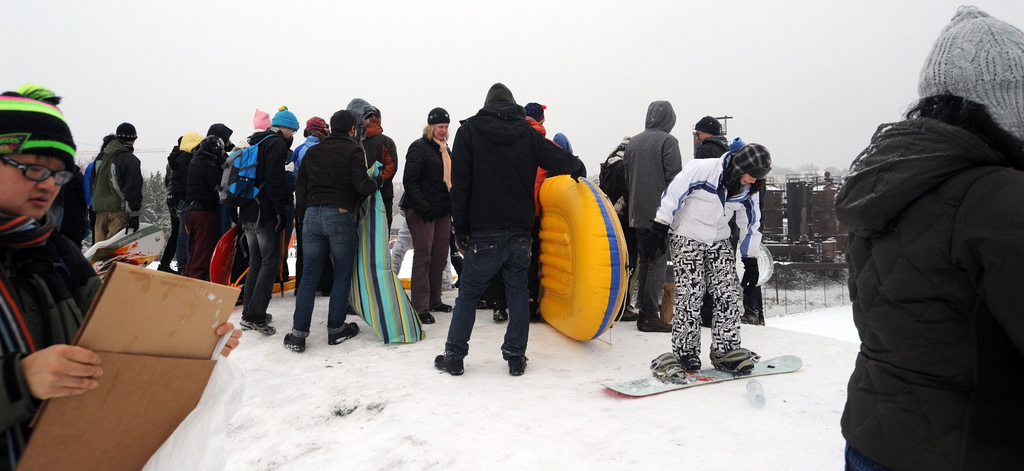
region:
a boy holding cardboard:
[0, 70, 261, 463]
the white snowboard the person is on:
[599, 350, 809, 398]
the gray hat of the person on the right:
[897, 0, 1019, 125]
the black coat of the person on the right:
[830, 97, 1021, 467]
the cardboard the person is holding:
[21, 263, 250, 466]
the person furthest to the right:
[828, 4, 1021, 467]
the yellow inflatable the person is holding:
[536, 170, 634, 347]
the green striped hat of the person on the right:
[0, 88, 98, 164]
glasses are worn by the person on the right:
[3, 152, 98, 197]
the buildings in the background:
[752, 167, 869, 307]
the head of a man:
[2, 83, 78, 243]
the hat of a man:
[2, 78, 86, 162]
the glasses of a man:
[11, 151, 81, 189]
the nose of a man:
[32, 168, 64, 197]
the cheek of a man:
[8, 162, 28, 202]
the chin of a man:
[17, 203, 55, 220]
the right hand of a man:
[32, 341, 110, 428]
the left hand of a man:
[190, 309, 260, 355]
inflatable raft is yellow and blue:
[535, 165, 635, 347]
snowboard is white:
[590, 348, 812, 391]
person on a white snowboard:
[614, 132, 798, 408]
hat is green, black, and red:
[1, 83, 79, 170]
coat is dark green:
[830, 103, 1021, 443]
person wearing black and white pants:
[650, 141, 765, 377]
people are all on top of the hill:
[10, 81, 1019, 468]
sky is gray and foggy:
[0, 7, 1019, 201]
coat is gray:
[621, 100, 673, 231]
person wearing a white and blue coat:
[664, 109, 764, 382]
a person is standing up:
[656, 141, 787, 391]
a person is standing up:
[0, 95, 131, 451]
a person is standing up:
[82, 111, 134, 258]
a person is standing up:
[110, 94, 167, 247]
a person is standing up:
[158, 101, 226, 267]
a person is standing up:
[223, 88, 301, 339]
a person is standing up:
[286, 95, 385, 351]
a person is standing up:
[404, 82, 461, 326]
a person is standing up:
[613, 95, 684, 321]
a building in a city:
[776, 171, 812, 239]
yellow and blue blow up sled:
[537, 167, 633, 346]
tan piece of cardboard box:
[6, 259, 244, 466]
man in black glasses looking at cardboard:
[4, 82, 240, 466]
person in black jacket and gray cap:
[827, 5, 1023, 464]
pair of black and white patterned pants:
[670, 229, 741, 365]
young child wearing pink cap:
[249, 106, 275, 130]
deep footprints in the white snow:
[211, 331, 446, 467]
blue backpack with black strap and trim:
[219, 131, 265, 224]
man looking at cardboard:
[2, 80, 236, 466]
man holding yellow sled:
[447, 85, 628, 384]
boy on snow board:
[605, 131, 820, 395]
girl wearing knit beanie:
[820, 1, 1020, 463]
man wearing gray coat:
[614, 98, 688, 336]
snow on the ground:
[15, 250, 894, 460]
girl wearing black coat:
[283, 105, 382, 350]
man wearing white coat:
[644, 142, 772, 377]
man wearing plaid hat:
[652, 140, 783, 381]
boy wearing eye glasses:
[8, 145, 101, 317]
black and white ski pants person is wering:
[666, 224, 746, 360]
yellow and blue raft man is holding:
[537, 173, 629, 344]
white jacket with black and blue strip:
[651, 153, 766, 258]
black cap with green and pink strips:
[0, 84, 82, 168]